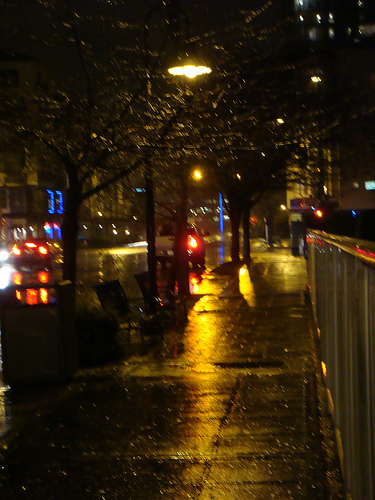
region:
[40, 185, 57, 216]
blue lights in a window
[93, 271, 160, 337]
park bench on the curb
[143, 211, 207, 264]
pick up truck driving in the rain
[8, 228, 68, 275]
car traveling in the rain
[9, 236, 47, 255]
tail lights of a car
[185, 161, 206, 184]
street light on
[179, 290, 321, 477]
the sidewalk is wet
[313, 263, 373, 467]
gate by the sidewalk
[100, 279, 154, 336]
the benches are black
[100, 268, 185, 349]
benches on the sidewalk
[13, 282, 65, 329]
reflection is on the street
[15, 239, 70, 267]
the car on the street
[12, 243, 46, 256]
lights on the car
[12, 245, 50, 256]
the lights are red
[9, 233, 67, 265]
car on a wet rainy road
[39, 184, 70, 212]
blue lights on a building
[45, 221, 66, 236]
blue and red lights on a building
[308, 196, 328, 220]
red lights on a building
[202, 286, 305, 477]
wet sidewalk at night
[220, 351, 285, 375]
man hole in the sidewalk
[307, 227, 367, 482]
metal railing along the sidewalk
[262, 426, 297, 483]
leaves laying on a wet sidewalk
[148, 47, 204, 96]
light on pole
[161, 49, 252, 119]
light on a metal pole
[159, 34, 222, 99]
pole with a light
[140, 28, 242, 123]
metal pole with light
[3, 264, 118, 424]
a garbage can on the sidewalk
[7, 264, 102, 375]
a trash can on a sidewalk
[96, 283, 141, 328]
a bench on teh sidewalk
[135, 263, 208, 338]
a benchon the sidewalk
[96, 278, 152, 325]
a metal bench on sidewalk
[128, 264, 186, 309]
a metal bench on the sidwalk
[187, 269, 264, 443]
yellow light reflected on the floor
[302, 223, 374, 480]
a rail on side the street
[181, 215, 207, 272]
red light on back a car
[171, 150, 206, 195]
street light is lit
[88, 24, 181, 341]
A tree in a city.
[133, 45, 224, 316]
A tree in a city.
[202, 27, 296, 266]
A tree in a city.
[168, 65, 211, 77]
Largest yellow tinted light through the trees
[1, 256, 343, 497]
Dark wet shiny long sidewalk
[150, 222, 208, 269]
Truck on the road with red tail lights illuminated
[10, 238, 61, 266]
Car in the road with red tail lights.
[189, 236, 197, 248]
Larger red illuminated truck tail light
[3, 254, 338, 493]
Long wet shiny sidewalk with yellow lights cast upon it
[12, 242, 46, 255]
Three red tail lights on a car.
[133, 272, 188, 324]
Black bench closest to the truck on the road.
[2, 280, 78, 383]
A large dark trash can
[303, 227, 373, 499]
Fence along the dark sidwalk.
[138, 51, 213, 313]
a sidewalk light on a pole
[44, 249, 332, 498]
light reflecting on a wet sidewalk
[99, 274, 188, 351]
park benches on a sidewalk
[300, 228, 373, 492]
the metal poles of a fence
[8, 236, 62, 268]
a car with its brake lights activated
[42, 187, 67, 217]
blue neon business sign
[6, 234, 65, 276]
a car on a wet street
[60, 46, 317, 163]
wet tree branches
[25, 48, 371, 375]
this is a city street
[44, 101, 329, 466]
this is a sidewalk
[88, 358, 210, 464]
the concrete is black